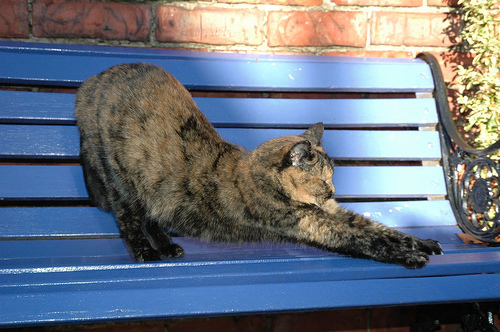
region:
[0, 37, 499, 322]
park bench is blue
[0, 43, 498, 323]
bench slates are wooden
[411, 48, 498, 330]
metal leg on bench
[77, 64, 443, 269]
the cat is black and gold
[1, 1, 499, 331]
red brick wall behind bench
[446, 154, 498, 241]
metal scrollwork on leg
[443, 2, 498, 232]
light green ivy on wall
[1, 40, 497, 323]
wooden slates are painted blue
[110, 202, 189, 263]
cats back paws are black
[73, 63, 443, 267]
cat is stretching on bench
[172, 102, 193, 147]
black fur on cat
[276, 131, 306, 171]
left ear on cat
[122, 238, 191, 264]
front feet on cat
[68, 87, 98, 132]
butt of multicolored cat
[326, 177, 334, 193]
cat has brown nose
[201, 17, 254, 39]
red brick on wall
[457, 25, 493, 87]
green bush by bench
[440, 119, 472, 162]
black bar on bench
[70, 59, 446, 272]
A cat is stretching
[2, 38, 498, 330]
A cat is on a bench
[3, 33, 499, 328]
The bench is blue and wooden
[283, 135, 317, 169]
Ear of a cat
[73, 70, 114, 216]
The tail of a cat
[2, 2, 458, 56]
Bricks on a wall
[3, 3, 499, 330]
A brick wall behind the bench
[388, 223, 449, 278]
Two paws of a cat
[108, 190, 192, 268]
A cat's back two legs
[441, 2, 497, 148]
Green plants on the wall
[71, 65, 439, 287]
cat stretching on blue bench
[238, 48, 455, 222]
sun shining on blue bench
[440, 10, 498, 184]
bush growing on right of bench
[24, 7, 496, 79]
red brick wall behind bench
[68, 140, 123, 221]
cat's tail tucked under cat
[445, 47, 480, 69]
small red berries on bush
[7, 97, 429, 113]
wooden panels of bench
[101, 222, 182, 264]
dark paws of cat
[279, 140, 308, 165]
pointed ear of cat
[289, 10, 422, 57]
the wall is made of bricks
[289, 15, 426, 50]
the bricks are brown in color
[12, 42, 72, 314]
this is a bench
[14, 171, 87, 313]
the bench is wooden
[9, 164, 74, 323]
the bench is blue in color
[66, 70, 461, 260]
this is a cat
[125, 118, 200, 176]
the cat is brown and grey in color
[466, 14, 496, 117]
these are some leaves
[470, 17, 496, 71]
the leaves are green in color